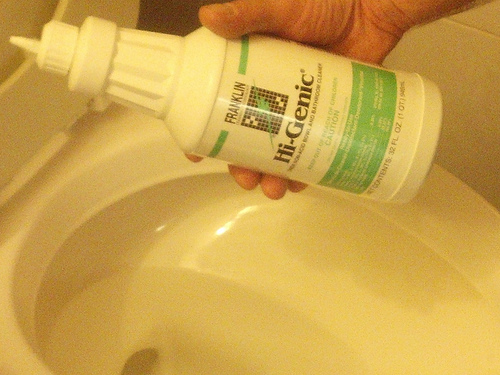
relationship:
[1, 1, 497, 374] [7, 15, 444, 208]
toilet behind bottle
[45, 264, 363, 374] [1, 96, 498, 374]
water inside toilet bowl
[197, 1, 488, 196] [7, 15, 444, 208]
hand holding bottle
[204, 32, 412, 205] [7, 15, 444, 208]
label on bottle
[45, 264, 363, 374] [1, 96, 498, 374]
water in toilet bowl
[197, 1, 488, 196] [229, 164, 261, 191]
hand has finger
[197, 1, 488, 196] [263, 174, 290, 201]
hand has finger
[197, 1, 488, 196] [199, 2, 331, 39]
hand has thumb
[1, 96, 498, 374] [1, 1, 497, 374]
toilet bowl inside toilet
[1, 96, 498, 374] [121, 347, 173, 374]
toilet bowl has drain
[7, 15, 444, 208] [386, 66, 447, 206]
bottle has bottom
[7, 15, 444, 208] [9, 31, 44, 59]
bottle has tip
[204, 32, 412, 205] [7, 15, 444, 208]
label stuck on bottle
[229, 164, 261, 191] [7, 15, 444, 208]
finger holding bottle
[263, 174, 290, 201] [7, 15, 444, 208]
finger holding bottle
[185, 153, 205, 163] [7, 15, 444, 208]
finger holding bottle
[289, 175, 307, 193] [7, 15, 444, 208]
finger holding bottle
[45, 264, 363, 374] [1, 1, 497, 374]
water in toilet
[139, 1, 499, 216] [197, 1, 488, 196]
wall by hand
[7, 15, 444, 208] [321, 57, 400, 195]
bottle has block area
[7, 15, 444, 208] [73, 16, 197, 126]
bottle has neck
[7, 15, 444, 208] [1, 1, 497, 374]
bottle by toilet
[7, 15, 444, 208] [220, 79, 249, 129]
bottle says word franklin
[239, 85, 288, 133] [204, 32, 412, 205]
grid printed on label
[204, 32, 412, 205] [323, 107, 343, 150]
label says caution